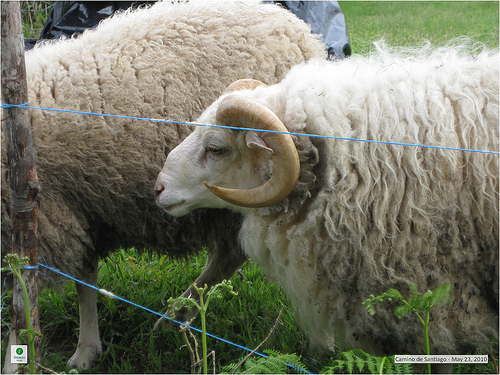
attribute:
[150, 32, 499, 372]
sheep — looking left, adult, large, white, curled, fluffy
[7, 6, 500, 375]
fence — wooden, blue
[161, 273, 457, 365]
weed — green, tall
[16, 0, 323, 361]
wool — dirty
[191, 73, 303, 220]
horns — long, brown, tan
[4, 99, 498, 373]
wire — blue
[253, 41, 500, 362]
hair — matted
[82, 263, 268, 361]
grass — pictured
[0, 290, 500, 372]
ground — pictured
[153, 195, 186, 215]
mouth — pictured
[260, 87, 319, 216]
neck — pictured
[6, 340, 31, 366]
sticker — pictured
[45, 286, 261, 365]
shade — pictured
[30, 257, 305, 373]
rope — blue